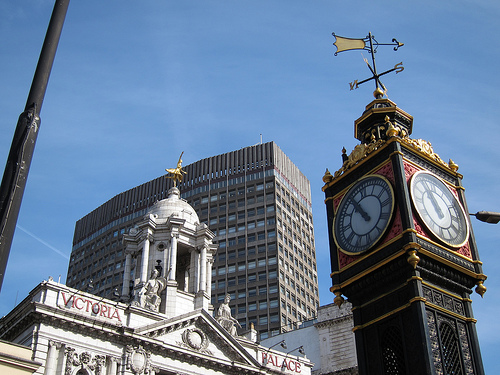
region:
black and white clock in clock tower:
[336, 169, 393, 249]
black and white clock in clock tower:
[400, 158, 470, 253]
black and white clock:
[395, 157, 471, 242]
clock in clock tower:
[402, 169, 474, 267]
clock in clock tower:
[327, 175, 405, 267]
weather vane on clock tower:
[318, 17, 414, 62]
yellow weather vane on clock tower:
[310, 20, 408, 58]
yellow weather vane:
[324, 19, 409, 64]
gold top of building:
[145, 139, 204, 181]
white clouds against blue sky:
[92, 40, 229, 125]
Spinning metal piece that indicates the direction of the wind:
[311, 9, 418, 99]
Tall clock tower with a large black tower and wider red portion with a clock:
[292, 25, 493, 373]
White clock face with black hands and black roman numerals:
[322, 172, 402, 254]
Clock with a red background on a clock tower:
[311, 167, 402, 255]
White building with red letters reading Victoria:
[51, 280, 123, 330]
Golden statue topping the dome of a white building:
[138, 142, 208, 242]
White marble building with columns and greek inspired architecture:
[118, 206, 210, 327]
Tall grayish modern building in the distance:
[204, 129, 311, 324]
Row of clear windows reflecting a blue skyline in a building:
[222, 220, 267, 241]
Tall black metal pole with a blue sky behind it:
[0, 4, 69, 296]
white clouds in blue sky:
[86, 12, 174, 68]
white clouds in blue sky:
[68, 56, 172, 121]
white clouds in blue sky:
[45, 117, 153, 157]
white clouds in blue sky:
[26, 205, 59, 265]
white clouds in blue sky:
[146, 9, 269, 70]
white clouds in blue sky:
[144, 85, 272, 138]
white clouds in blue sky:
[256, 86, 353, 120]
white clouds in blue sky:
[425, 18, 465, 108]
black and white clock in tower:
[396, 153, 486, 264]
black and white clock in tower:
[331, 172, 399, 243]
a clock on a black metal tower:
[329, 136, 487, 373]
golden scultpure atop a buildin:
[168, 150, 190, 185]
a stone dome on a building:
[144, 190, 201, 225]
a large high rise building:
[64, 140, 316, 332]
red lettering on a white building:
[60, 289, 122, 323]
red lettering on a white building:
[256, 350, 302, 371]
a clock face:
[408, 167, 467, 244]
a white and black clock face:
[332, 175, 395, 252]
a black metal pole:
[1, 0, 68, 307]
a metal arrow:
[330, 31, 405, 58]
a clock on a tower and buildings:
[5, 23, 492, 371]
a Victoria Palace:
[21, 154, 306, 374]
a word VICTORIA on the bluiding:
[51, 288, 125, 324]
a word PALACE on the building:
[253, 345, 303, 374]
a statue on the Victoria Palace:
[215, 285, 242, 337]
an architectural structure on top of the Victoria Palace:
[122, 155, 242, 326]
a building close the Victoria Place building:
[212, 148, 315, 318]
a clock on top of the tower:
[406, 145, 471, 245]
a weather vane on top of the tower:
[327, 24, 419, 92]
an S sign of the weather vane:
[388, 60, 408, 75]